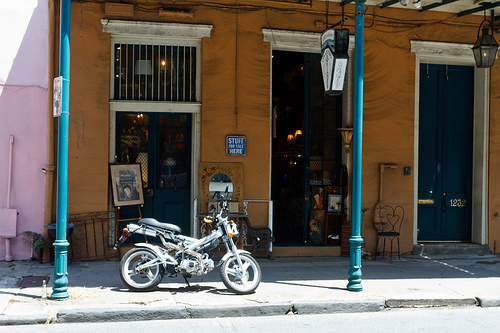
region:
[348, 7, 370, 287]
a blue metal support post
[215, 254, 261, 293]
the wheel of a motorcycle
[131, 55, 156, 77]
a lampshade in a window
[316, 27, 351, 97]
a suspended business sign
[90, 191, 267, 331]
a motorcycle on a sidewalk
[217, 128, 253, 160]
a sign on a building wall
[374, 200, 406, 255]
a black metal framed chair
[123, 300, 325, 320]
a curb by the road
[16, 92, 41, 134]
the pink facade of a building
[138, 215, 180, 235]
the seat of a motorcycle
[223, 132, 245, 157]
square+semi-grungey bright blue STUFF FOR SALE HERE sign on lively painted wall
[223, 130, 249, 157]
STUFF FOR SALE HERE sign is 3d, comes up from its wall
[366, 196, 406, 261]
heart-shaped back of vintage vanity chair on sidewalk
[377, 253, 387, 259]
wobbly vanity chair leg stabilized by small bright red thing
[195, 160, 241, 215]
round mirror has ornate painted square wooden frame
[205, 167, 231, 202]
mirror reflects motorcycle handles, wall beyond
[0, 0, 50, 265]
dusty rose wall with electrical fusebox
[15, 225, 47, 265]
small, large-leafed plant grows beside dusty pink wall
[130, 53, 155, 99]
lamp with white shade in top window of old lost boho store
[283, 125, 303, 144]
yellow+orange lamps alight inside old lost boho store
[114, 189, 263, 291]
motorcycle parked on sidewalk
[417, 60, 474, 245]
blue door with number 1232 on it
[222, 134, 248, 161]
blue sign with white lettering on side of building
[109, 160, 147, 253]
easel displaying art work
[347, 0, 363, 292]
tall blue pole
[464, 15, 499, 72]
old fashioned hanging lamp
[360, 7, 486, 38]
wiring run near top of wall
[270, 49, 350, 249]
open doorway to shop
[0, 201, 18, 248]
electrical wiring box painted pink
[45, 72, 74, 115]
sign hung on blue pole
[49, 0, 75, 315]
tall blue post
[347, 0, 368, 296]
tall blue post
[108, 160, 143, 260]
painting on an easle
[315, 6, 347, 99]
wedge shaped sign hanging from awning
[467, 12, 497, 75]
carriage lamp of black iron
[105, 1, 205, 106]
white slats over a window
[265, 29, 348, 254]
open door leading into building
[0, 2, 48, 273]
wall painted pink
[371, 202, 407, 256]
child sized wrought iron chair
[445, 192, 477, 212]
the numbers 1232 in white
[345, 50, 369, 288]
a bright blue pole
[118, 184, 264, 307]
a parked motorcycle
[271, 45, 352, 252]
a tall door half opened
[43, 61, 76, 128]
a white sign attached to pole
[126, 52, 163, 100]
a lamp with a white lamp shade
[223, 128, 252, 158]
a blue square sign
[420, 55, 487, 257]
a blue tall door that is closed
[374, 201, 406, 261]
a metal chair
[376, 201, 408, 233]
a heart shape